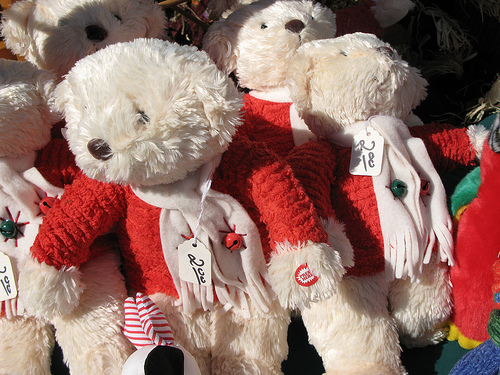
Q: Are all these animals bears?
A: Yes, all the animals are bears.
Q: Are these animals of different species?
A: No, all the animals are bears.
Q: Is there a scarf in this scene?
A: Yes, there is a scarf.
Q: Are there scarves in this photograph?
A: Yes, there is a scarf.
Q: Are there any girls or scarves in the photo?
A: Yes, there is a scarf.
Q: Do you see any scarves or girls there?
A: Yes, there is a scarf.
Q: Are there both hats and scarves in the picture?
A: No, there is a scarf but no hats.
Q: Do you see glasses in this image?
A: No, there are no glasses.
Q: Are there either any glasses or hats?
A: No, there are no glasses or hats.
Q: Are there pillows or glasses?
A: No, there are no glasses or pillows.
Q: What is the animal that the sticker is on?
A: The animal is a bear.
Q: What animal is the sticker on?
A: The sticker is on the bear.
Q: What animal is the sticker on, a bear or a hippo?
A: The sticker is on a bear.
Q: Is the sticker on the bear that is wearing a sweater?
A: Yes, the sticker is on the bear.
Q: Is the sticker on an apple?
A: No, the sticker is on the bear.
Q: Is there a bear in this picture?
A: Yes, there is a bear.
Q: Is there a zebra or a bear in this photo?
A: Yes, there is a bear.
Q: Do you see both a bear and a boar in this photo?
A: No, there is a bear but no boars.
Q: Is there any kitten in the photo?
A: No, there are no kittens.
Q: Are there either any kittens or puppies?
A: No, there are no kittens or puppies.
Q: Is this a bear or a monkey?
A: This is a bear.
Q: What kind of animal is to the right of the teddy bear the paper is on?
A: The animal is a bear.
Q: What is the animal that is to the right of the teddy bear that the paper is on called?
A: The animal is a bear.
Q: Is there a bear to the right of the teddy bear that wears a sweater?
A: Yes, there is a bear to the right of the teddy bear.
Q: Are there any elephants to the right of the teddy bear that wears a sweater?
A: No, there is a bear to the right of the teddy bear.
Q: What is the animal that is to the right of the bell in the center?
A: The animal is a bear.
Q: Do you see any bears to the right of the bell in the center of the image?
A: Yes, there is a bear to the right of the bell.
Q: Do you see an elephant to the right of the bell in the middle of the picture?
A: No, there is a bear to the right of the bell.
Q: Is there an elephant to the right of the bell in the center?
A: No, there is a bear to the right of the bell.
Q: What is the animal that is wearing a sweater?
A: The animal is a bear.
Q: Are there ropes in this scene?
A: No, there are no ropes.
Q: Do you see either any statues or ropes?
A: No, there are no ropes or statues.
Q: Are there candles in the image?
A: No, there are no candles.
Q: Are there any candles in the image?
A: No, there are no candles.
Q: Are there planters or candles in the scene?
A: No, there are no candles or planters.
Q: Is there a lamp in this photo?
A: No, there are no lamps.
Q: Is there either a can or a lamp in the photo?
A: No, there are no lamps or cans.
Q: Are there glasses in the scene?
A: No, there are no glasses.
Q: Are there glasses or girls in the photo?
A: No, there are no glasses or girls.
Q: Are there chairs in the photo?
A: No, there are no chairs.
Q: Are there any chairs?
A: No, there are no chairs.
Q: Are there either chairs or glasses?
A: No, there are no chairs or glasses.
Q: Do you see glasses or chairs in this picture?
A: No, there are no chairs or glasses.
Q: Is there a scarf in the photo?
A: Yes, there is a scarf.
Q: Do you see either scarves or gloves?
A: Yes, there is a scarf.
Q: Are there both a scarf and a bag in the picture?
A: No, there is a scarf but no bags.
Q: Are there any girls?
A: No, there are no girls.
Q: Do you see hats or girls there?
A: No, there are no girls or hats.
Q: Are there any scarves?
A: Yes, there is a scarf.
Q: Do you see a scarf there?
A: Yes, there is a scarf.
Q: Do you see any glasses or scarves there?
A: Yes, there is a scarf.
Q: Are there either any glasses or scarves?
A: Yes, there is a scarf.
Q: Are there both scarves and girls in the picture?
A: No, there is a scarf but no girls.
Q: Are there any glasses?
A: No, there are no glasses.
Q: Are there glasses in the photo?
A: No, there are no glasses.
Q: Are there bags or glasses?
A: No, there are no glasses or bags.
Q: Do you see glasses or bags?
A: No, there are no glasses or bags.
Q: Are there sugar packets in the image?
A: No, there are no sugar packets.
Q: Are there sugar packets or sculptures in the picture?
A: No, there are no sugar packets or sculptures.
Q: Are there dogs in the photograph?
A: No, there are no dogs.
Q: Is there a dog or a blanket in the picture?
A: No, there are no dogs or blankets.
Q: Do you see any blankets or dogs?
A: No, there are no dogs or blankets.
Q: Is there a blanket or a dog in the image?
A: No, there are no dogs or blankets.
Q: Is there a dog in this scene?
A: No, there are no dogs.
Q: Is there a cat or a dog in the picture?
A: No, there are no dogs or cats.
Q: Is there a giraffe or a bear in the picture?
A: Yes, there is a bear.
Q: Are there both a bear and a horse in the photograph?
A: No, there is a bear but no horses.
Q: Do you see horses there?
A: No, there are no horses.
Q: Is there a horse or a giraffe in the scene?
A: No, there are no horses or giraffes.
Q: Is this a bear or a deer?
A: This is a bear.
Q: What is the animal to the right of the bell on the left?
A: The animal is a bear.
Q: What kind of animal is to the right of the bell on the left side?
A: The animal is a bear.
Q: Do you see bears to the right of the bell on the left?
A: Yes, there is a bear to the right of the bell.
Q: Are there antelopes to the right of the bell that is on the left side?
A: No, there is a bear to the right of the bell.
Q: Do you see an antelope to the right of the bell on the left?
A: No, there is a bear to the right of the bell.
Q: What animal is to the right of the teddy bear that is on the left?
A: The animal is a bear.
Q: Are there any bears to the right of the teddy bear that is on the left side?
A: Yes, there is a bear to the right of the teddy bear.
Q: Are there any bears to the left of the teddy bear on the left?
A: No, the bear is to the right of the teddy bear.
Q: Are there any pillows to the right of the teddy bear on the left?
A: No, there is a bear to the right of the teddy bear.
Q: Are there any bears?
A: Yes, there is a bear.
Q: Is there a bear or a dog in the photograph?
A: Yes, there is a bear.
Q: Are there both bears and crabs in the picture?
A: No, there is a bear but no crabs.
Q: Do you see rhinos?
A: No, there are no rhinos.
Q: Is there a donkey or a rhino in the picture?
A: No, there are no rhinos or donkeys.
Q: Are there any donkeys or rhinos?
A: No, there are no rhinos or donkeys.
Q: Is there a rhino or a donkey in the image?
A: No, there are no rhinos or donkeys.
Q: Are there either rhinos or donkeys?
A: No, there are no rhinos or donkeys.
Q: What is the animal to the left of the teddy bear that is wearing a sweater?
A: The animal is a bear.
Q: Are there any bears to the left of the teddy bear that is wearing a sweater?
A: Yes, there is a bear to the left of the teddy bear.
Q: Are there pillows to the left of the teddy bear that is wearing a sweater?
A: No, there is a bear to the left of the teddy bear.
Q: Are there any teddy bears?
A: Yes, there is a teddy bear.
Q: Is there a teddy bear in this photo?
A: Yes, there is a teddy bear.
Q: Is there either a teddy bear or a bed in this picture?
A: Yes, there is a teddy bear.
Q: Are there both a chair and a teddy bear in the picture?
A: No, there is a teddy bear but no chairs.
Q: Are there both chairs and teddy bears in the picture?
A: No, there is a teddy bear but no chairs.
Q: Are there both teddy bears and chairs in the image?
A: No, there is a teddy bear but no chairs.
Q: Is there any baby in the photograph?
A: No, there are no babies.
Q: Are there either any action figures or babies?
A: No, there are no babies or action figures.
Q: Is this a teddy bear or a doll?
A: This is a teddy bear.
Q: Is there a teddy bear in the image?
A: Yes, there is a teddy bear.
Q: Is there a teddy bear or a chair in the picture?
A: Yes, there is a teddy bear.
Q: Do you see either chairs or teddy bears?
A: Yes, there is a teddy bear.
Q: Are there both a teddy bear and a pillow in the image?
A: No, there is a teddy bear but no pillows.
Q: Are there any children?
A: No, there are no children.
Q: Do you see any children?
A: No, there are no children.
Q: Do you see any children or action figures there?
A: No, there are no children or action figures.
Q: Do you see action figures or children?
A: No, there are no children or action figures.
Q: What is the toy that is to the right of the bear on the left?
A: The toy is a teddy bear.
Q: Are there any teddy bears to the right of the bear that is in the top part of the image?
A: Yes, there is a teddy bear to the right of the bear.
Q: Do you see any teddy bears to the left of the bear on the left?
A: No, the teddy bear is to the right of the bear.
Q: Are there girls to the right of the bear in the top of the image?
A: No, there is a teddy bear to the right of the bear.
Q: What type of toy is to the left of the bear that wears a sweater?
A: The toy is a teddy bear.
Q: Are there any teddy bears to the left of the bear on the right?
A: Yes, there is a teddy bear to the left of the bear.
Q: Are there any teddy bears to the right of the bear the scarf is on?
A: No, the teddy bear is to the left of the bear.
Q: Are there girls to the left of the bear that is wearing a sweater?
A: No, there is a teddy bear to the left of the bear.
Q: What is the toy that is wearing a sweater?
A: The toy is a teddy bear.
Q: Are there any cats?
A: No, there are no cats.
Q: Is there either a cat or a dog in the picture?
A: No, there are no cats or dogs.